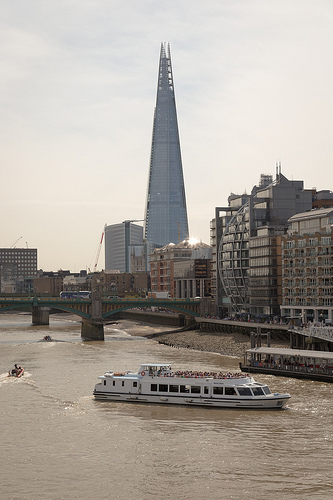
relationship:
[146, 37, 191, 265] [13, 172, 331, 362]
building in a city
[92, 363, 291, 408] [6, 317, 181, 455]
boats on a river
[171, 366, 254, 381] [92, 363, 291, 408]
people on a boats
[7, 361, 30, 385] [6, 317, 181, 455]
boat on river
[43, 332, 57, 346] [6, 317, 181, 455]
boat on river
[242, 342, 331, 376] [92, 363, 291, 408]
boat on or side of boats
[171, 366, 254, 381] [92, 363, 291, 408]
people on boats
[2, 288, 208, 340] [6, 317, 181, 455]
bridge over river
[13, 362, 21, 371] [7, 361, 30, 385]
people in boat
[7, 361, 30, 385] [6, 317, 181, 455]
boat in river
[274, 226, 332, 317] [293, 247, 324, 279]
building has windows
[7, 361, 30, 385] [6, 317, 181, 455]
boat floating on river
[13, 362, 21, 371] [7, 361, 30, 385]
people standing in a boat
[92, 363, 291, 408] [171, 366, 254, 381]
boats carrying people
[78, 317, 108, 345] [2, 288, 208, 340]
concrete support for bridge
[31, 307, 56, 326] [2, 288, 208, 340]
concrete support for bridge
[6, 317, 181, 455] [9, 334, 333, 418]
river with boats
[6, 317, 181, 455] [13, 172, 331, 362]
river next to city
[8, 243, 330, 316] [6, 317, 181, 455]
buildings near river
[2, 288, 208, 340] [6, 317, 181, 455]
bridge over a river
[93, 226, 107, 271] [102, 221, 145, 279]
crane working on a building